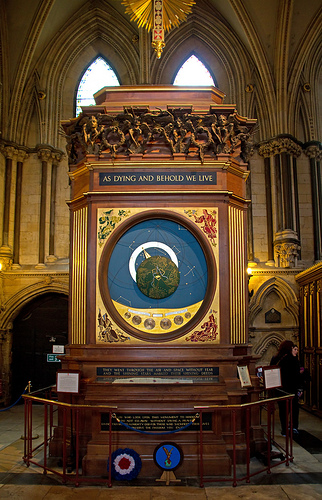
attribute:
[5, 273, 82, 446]
doorway — large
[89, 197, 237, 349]
device — clock like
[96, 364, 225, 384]
writing — more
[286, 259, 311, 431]
case — display